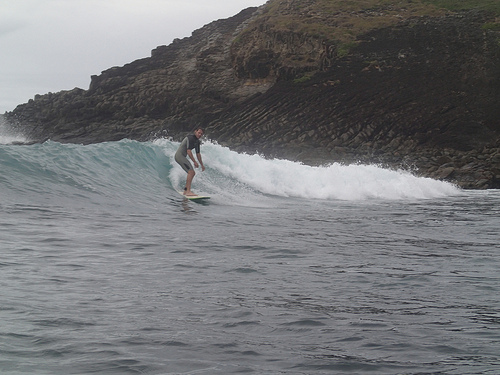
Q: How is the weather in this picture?
A: It is overcast.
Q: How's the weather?
A: It is overcast.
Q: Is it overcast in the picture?
A: Yes, it is overcast.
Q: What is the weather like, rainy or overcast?
A: It is overcast.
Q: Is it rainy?
A: No, it is overcast.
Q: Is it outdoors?
A: Yes, it is outdoors.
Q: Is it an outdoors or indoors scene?
A: It is outdoors.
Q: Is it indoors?
A: No, it is outdoors.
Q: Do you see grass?
A: Yes, there is grass.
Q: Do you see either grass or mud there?
A: Yes, there is grass.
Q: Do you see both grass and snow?
A: No, there is grass but no snow.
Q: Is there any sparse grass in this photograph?
A: Yes, there is sparse grass.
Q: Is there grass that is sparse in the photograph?
A: Yes, there is sparse grass.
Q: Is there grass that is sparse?
A: Yes, there is grass that is sparse.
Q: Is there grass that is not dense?
A: Yes, there is sparse grass.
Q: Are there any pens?
A: No, there are no pens.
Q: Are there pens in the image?
A: No, there are no pens.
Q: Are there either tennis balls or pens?
A: No, there are no pens or tennis balls.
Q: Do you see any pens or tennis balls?
A: No, there are no pens or tennis balls.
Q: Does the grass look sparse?
A: Yes, the grass is sparse.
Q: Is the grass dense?
A: No, the grass is sparse.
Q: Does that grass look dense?
A: No, the grass is sparse.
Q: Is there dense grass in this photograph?
A: No, there is grass but it is sparse.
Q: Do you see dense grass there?
A: No, there is grass but it is sparse.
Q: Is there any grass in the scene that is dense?
A: No, there is grass but it is sparse.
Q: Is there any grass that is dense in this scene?
A: No, there is grass but it is sparse.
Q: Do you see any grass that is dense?
A: No, there is grass but it is sparse.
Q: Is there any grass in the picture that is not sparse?
A: No, there is grass but it is sparse.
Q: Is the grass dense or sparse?
A: The grass is sparse.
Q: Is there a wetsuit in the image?
A: Yes, there is a wetsuit.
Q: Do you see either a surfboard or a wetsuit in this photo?
A: Yes, there is a wetsuit.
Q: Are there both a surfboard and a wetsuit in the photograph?
A: Yes, there are both a wetsuit and a surfboard.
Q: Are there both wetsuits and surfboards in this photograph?
A: Yes, there are both a wetsuit and a surfboard.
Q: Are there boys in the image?
A: No, there are no boys.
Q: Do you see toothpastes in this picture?
A: No, there are no toothpastes.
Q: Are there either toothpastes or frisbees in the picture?
A: No, there are no toothpastes or frisbees.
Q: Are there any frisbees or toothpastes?
A: No, there are no toothpastes or frisbees.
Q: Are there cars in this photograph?
A: No, there are no cars.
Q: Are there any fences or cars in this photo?
A: No, there are no cars or fences.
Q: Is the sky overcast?
A: Yes, the sky is overcast.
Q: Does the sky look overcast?
A: Yes, the sky is overcast.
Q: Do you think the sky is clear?
A: No, the sky is overcast.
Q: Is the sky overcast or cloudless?
A: The sky is overcast.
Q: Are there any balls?
A: No, there are no balls.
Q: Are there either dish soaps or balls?
A: No, there are no balls or dish soaps.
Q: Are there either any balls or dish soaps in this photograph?
A: No, there are no balls or dish soaps.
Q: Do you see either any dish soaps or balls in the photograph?
A: No, there are no balls or dish soaps.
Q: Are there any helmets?
A: No, there are no helmets.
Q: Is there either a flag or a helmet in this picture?
A: No, there are no helmets or flags.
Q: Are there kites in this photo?
A: No, there are no kites.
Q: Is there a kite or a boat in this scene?
A: No, there are no kites or boats.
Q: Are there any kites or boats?
A: No, there are no kites or boats.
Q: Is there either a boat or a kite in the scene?
A: No, there are no kites or boats.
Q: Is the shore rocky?
A: Yes, the shore is rocky.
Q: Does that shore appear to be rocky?
A: Yes, the shore is rocky.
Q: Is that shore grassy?
A: No, the shore is rocky.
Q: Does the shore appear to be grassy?
A: No, the shore is rocky.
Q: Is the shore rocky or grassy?
A: The shore is rocky.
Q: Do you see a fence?
A: No, there are no fences.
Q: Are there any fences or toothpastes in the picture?
A: No, there are no fences or toothpastes.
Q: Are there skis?
A: No, there are no skis.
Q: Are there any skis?
A: No, there are no skis.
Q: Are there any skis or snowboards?
A: No, there are no skis or snowboards.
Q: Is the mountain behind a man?
A: Yes, the mountain is behind a man.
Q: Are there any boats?
A: No, there are no boats.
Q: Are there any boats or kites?
A: No, there are no boats or kites.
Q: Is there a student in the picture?
A: No, there are no students.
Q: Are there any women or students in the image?
A: No, there are no students or women.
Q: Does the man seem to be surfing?
A: Yes, the man is surfing.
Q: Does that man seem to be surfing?
A: Yes, the man is surfing.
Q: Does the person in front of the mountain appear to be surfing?
A: Yes, the man is surfing.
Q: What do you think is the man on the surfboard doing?
A: The man is surfing.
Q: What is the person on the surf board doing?
A: The man is surfing.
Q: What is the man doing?
A: The man is surfing.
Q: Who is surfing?
A: The man is surfing.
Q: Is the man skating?
A: No, the man is surfing.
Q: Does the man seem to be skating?
A: No, the man is surfing.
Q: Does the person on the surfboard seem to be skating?
A: No, the man is surfing.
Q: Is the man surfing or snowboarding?
A: The man is surfing.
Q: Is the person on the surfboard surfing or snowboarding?
A: The man is surfing.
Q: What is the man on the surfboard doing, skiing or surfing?
A: The man is surfing.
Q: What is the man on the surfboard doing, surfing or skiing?
A: The man is surfing.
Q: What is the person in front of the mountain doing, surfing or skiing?
A: The man is surfing.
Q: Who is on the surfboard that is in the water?
A: The man is on the surfboard.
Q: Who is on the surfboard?
A: The man is on the surfboard.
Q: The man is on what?
A: The man is on the surf board.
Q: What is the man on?
A: The man is on the surf board.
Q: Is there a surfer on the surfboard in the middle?
A: No, there is a man on the surfboard.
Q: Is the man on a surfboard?
A: Yes, the man is on a surfboard.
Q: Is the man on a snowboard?
A: No, the man is on a surfboard.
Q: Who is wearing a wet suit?
A: The man is wearing a wet suit.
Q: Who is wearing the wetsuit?
A: The man is wearing a wet suit.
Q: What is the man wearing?
A: The man is wearing a wetsuit.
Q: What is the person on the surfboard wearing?
A: The man is wearing a wetsuit.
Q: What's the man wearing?
A: The man is wearing a wetsuit.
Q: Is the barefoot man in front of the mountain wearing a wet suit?
A: Yes, the man is wearing a wet suit.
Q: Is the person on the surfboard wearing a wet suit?
A: Yes, the man is wearing a wet suit.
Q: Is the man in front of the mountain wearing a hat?
A: No, the man is wearing a wet suit.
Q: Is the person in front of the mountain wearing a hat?
A: No, the man is wearing a wet suit.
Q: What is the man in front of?
A: The man is in front of the mountain.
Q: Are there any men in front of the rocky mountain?
A: Yes, there is a man in front of the mountain.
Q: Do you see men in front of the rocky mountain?
A: Yes, there is a man in front of the mountain.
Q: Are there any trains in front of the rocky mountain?
A: No, there is a man in front of the mountain.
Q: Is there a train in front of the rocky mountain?
A: No, there is a man in front of the mountain.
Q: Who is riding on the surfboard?
A: The man is riding on the surfboard.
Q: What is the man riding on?
A: The man is riding on the surfboard.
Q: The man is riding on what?
A: The man is riding on the surfboard.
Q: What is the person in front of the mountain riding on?
A: The man is riding on the surfboard.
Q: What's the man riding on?
A: The man is riding on the surfboard.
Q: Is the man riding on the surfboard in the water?
A: Yes, the man is riding on the surf board.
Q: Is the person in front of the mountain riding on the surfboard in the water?
A: Yes, the man is riding on the surf board.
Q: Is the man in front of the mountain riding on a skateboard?
A: No, the man is riding on the surf board.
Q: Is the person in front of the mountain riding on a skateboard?
A: No, the man is riding on the surf board.